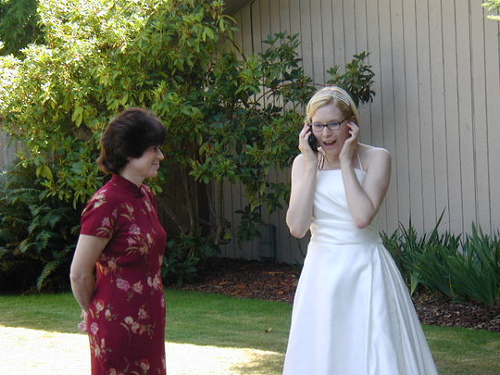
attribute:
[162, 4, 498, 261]
fence — wooden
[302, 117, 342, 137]
eyeglasses — pair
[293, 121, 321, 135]
phone — small, black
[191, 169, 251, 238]
bamboo — stand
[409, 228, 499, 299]
garden — strip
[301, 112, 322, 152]
phone — cell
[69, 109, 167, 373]
woman — back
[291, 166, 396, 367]
dress — long, silk, white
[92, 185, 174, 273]
dress — red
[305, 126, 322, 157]
phone — black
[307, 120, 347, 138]
glasses — pair, eye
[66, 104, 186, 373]
woman — standing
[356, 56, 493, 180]
fence — white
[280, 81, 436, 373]
bride — excited, young, blonde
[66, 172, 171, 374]
dress — flowered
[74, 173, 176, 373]
dress — red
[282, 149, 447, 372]
dress — white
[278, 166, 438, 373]
dress — white